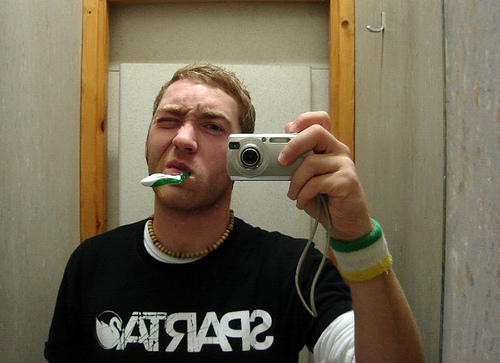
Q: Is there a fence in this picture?
A: No, there are no fences.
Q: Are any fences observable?
A: No, there are no fences.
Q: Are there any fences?
A: No, there are no fences.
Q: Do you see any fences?
A: No, there are no fences.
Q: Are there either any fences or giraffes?
A: No, there are no fences or giraffes.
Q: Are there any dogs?
A: No, there are no dogs.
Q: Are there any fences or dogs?
A: No, there are no dogs or fences.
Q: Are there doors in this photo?
A: Yes, there is a door.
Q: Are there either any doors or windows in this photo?
A: Yes, there is a door.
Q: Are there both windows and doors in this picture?
A: No, there is a door but no windows.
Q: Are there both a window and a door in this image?
A: No, there is a door but no windows.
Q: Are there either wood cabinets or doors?
A: Yes, there is a wood door.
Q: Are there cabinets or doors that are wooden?
A: Yes, the door is wooden.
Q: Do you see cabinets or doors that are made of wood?
A: Yes, the door is made of wood.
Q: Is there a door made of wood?
A: Yes, there is a door that is made of wood.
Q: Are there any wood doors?
A: Yes, there is a door that is made of wood.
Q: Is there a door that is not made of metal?
A: Yes, there is a door that is made of wood.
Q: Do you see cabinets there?
A: No, there are no cabinets.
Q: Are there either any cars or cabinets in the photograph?
A: No, there are no cabinets or cars.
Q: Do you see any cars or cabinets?
A: No, there are no cabinets or cars.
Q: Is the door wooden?
A: Yes, the door is wooden.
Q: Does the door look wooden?
A: Yes, the door is wooden.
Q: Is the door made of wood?
A: Yes, the door is made of wood.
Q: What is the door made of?
A: The door is made of wood.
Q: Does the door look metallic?
A: No, the door is wooden.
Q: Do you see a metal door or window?
A: No, there is a door but it is wooden.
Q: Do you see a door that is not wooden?
A: No, there is a door but it is wooden.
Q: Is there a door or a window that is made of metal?
A: No, there is a door but it is made of wood.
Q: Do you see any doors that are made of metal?
A: No, there is a door but it is made of wood.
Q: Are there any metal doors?
A: No, there is a door but it is made of wood.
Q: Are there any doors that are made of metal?
A: No, there is a door but it is made of wood.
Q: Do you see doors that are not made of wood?
A: No, there is a door but it is made of wood.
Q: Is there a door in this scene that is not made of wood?
A: No, there is a door but it is made of wood.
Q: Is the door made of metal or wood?
A: The door is made of wood.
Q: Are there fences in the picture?
A: No, there are no fences.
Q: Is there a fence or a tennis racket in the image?
A: No, there are no fences or rackets.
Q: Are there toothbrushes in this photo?
A: Yes, there is a toothbrush.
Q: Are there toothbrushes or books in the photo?
A: Yes, there is a toothbrush.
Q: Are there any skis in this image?
A: No, there are no skis.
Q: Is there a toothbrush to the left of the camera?
A: Yes, there is a toothbrush to the left of the camera.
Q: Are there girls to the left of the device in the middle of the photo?
A: No, there is a toothbrush to the left of the camera.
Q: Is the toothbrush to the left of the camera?
A: Yes, the toothbrush is to the left of the camera.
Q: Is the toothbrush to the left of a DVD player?
A: No, the toothbrush is to the left of the camera.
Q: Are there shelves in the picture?
A: No, there are no shelves.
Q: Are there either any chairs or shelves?
A: No, there are no shelves or chairs.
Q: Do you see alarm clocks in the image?
A: No, there are no alarm clocks.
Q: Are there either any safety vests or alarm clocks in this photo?
A: No, there are no alarm clocks or safety vests.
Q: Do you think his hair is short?
A: Yes, the hair is short.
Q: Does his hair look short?
A: Yes, the hair is short.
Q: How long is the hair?
A: The hair is short.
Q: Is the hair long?
A: No, the hair is short.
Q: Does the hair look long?
A: No, the hair is short.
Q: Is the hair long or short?
A: The hair is short.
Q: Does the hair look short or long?
A: The hair is short.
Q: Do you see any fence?
A: No, there are no fences.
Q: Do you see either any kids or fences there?
A: No, there are no fences or kids.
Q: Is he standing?
A: Yes, the man is standing.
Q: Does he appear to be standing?
A: Yes, the man is standing.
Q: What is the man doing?
A: The man is standing.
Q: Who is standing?
A: The man is standing.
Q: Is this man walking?
A: No, the man is standing.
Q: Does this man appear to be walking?
A: No, the man is standing.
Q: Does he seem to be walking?
A: No, the man is standing.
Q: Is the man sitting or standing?
A: The man is standing.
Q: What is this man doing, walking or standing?
A: The man is standing.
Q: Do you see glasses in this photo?
A: No, there are no glasses.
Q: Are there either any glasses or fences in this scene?
A: No, there are no glasses or fences.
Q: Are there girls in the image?
A: No, there are no girls.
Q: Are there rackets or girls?
A: No, there are no girls or rackets.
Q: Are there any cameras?
A: Yes, there is a camera.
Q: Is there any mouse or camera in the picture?
A: Yes, there is a camera.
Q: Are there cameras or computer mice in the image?
A: Yes, there is a camera.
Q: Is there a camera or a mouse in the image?
A: Yes, there is a camera.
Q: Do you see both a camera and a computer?
A: No, there is a camera but no computers.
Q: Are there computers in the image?
A: No, there are no computers.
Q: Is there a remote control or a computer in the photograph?
A: No, there are no computers or remote controls.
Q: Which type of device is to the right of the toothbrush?
A: The device is a camera.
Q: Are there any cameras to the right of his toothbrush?
A: Yes, there is a camera to the right of the toothbrush.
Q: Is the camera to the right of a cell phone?
A: No, the camera is to the right of the toothbrush.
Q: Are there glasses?
A: No, there are no glasses.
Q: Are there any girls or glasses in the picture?
A: No, there are no glasses or girls.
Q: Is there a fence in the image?
A: No, there are no fences.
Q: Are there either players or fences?
A: No, there are no fences or players.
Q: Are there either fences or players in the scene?
A: No, there are no fences or players.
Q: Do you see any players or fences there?
A: No, there are no fences or players.